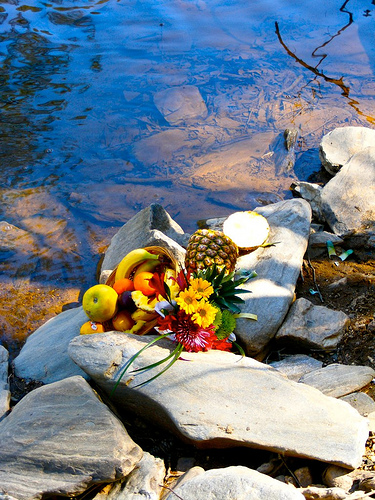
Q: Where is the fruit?
A: On the rocks.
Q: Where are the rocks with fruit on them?
A: On the river bed.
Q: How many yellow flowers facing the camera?
A: 3.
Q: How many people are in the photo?
A: Zero.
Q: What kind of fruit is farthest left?
A: Lemon.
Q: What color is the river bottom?
A: Brown.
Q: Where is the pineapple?
A: Above the flowers.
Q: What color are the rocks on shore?
A: Grey.